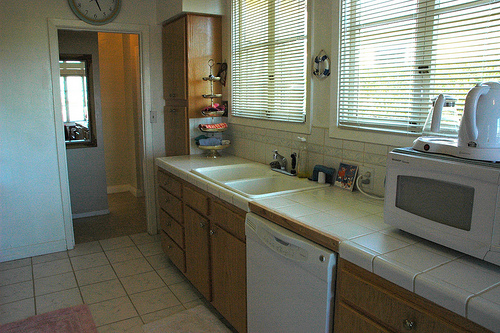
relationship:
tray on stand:
[203, 69, 221, 80] [197, 57, 227, 163]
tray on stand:
[203, 93, 224, 99] [197, 57, 227, 163]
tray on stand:
[205, 107, 225, 119] [197, 57, 227, 163]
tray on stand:
[199, 122, 227, 133] [197, 57, 227, 163]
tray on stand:
[195, 142, 226, 151] [197, 57, 227, 163]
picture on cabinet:
[335, 163, 357, 190] [296, 174, 414, 261]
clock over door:
[66, 1, 122, 25] [53, 25, 147, 248]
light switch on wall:
[148, 110, 160, 125] [4, 2, 167, 267]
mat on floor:
[0, 302, 96, 333] [0, 231, 235, 331]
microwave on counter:
[381, 144, 497, 268] [339, 221, 499, 329]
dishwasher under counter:
[238, 212, 332, 327] [250, 185, 393, 251]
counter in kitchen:
[152, 146, 499, 331] [3, 2, 499, 331]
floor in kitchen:
[0, 231, 235, 331] [3, 2, 499, 331]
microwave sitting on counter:
[381, 144, 497, 268] [152, 146, 499, 331]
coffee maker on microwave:
[457, 71, 492, 158] [370, 151, 497, 261]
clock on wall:
[62, 2, 129, 27] [4, 2, 167, 267]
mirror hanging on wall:
[58, 53, 95, 149] [7, 24, 57, 238]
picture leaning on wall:
[332, 160, 359, 190] [219, 7, 496, 185]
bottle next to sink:
[286, 133, 315, 181] [185, 151, 337, 201]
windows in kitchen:
[246, 16, 486, 141] [4, 0, 438, 330]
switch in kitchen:
[148, 103, 165, 132] [4, 0, 438, 330]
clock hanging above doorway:
[66, 1, 122, 25] [47, 22, 152, 240]